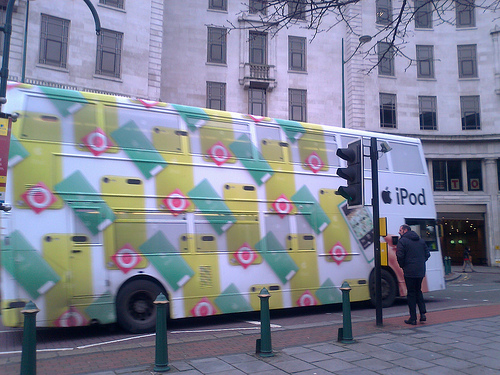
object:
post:
[339, 281, 355, 344]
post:
[257, 287, 275, 358]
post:
[20, 300, 40, 374]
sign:
[336, 138, 365, 209]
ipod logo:
[381, 187, 428, 206]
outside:
[0, 0, 500, 375]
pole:
[369, 137, 383, 327]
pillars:
[153, 292, 169, 373]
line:
[0, 318, 280, 356]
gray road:
[0, 265, 499, 375]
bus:
[0, 79, 445, 335]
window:
[418, 95, 438, 131]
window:
[34, 12, 70, 74]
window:
[91, 27, 124, 84]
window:
[96, 0, 129, 13]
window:
[205, 26, 228, 67]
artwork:
[0, 79, 445, 334]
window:
[457, 44, 479, 81]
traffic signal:
[335, 137, 390, 327]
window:
[460, 95, 482, 131]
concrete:
[0, 303, 500, 375]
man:
[396, 224, 431, 325]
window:
[416, 44, 438, 81]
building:
[0, 0, 500, 270]